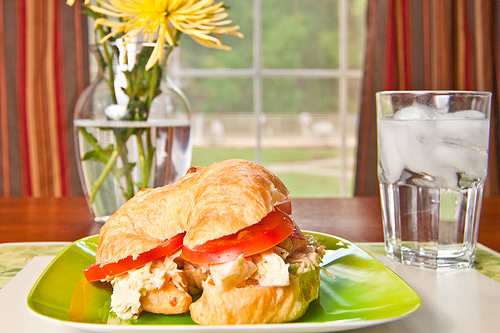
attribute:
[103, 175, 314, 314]
sandwich — croissant, tuna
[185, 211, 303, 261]
tomato — red, sliced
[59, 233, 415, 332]
plate — green, lime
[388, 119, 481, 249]
water — iced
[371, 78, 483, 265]
glass — clear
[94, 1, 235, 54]
flowers — yellow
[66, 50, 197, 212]
vase — clear, glass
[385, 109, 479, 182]
ice cubes — floating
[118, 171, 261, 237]
croissant — golden, bun, split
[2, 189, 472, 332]
table — wooden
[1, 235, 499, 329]
placemat — plastic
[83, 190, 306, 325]
lunch — tasty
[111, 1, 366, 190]
window — glass